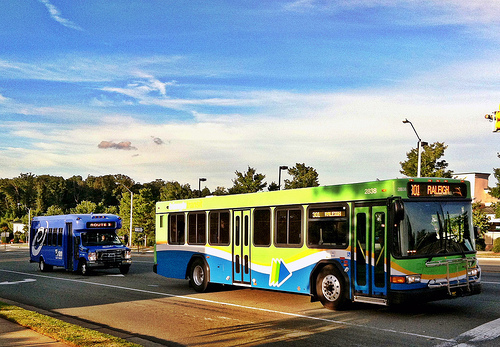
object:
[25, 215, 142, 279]
bus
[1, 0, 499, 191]
sky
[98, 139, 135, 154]
clouds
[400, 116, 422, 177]
street lamp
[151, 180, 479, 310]
bus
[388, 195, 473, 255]
window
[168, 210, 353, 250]
window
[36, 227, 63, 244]
window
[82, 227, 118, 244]
window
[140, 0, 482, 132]
bus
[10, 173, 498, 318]
bus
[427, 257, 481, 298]
bike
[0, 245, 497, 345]
street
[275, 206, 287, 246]
window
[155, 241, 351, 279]
white swirl